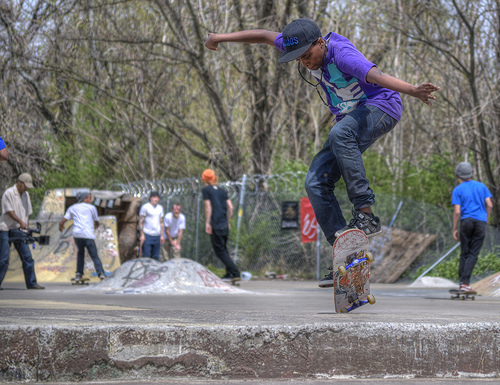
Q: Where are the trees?
A: Background.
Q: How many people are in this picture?
A: Seven.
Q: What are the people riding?
A: Skateboards.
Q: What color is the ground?
A: Gray.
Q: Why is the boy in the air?
A: He is jumping.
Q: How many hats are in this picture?
A: Four.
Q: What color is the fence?
A: Silver.